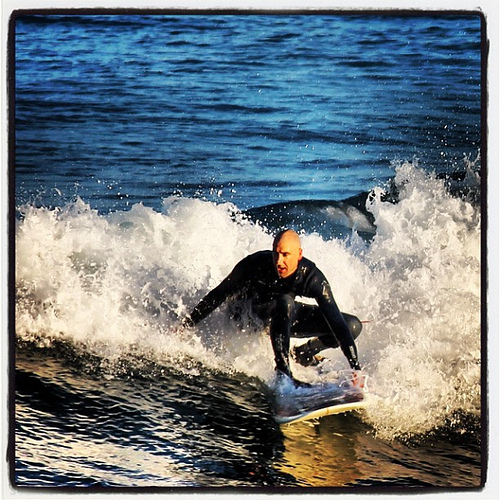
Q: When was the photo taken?
A: Daytime.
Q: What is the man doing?
A: Surfing.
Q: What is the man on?
A: Surfboard.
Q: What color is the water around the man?
A: White.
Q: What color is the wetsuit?
A: Black.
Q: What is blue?
A: Water.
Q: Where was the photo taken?
A: Beach.